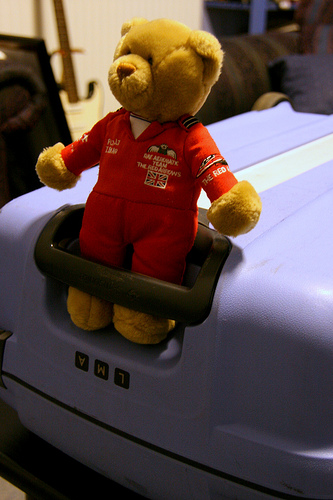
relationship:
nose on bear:
[116, 61, 135, 80] [34, 15, 262, 344]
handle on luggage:
[29, 198, 243, 332] [0, 104, 333, 496]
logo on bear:
[147, 169, 166, 190] [34, 15, 262, 344]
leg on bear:
[115, 211, 198, 345] [34, 15, 262, 344]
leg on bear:
[66, 200, 125, 331] [34, 15, 262, 344]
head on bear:
[106, 16, 224, 126] [56, 22, 261, 239]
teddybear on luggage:
[111, 31, 223, 200] [0, 104, 333, 496]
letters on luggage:
[57, 347, 132, 391] [0, 92, 332, 496]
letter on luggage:
[93, 358, 109, 381] [0, 92, 332, 496]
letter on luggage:
[111, 367, 129, 386] [0, 92, 332, 496]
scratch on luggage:
[251, 257, 279, 276] [0, 92, 332, 496]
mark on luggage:
[273, 477, 303, 491] [0, 92, 332, 496]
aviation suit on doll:
[60, 108, 238, 285] [35, 16, 263, 344]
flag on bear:
[143, 167, 168, 186] [34, 15, 262, 344]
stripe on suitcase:
[228, 140, 318, 182] [201, 123, 329, 351]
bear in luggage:
[34, 15, 262, 344] [0, 104, 333, 496]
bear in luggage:
[35, 16, 261, 344] [168, 104, 318, 312]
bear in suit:
[34, 15, 262, 344] [60, 103, 236, 294]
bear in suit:
[34, 15, 262, 344] [58, 109, 233, 285]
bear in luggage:
[35, 16, 261, 344] [1, 101, 326, 374]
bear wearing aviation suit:
[35, 16, 261, 344] [32, 17, 262, 345]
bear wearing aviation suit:
[34, 15, 262, 344] [59, 108, 239, 285]